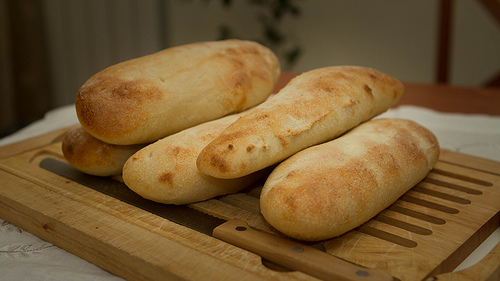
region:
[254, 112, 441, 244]
a loaf of bread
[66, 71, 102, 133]
a dark brown end of a bread loaf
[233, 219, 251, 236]
a bolt in the wood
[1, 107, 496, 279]
a brown wooden cutting board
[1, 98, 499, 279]
a white table cloth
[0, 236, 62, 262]
a pattern on the table cloth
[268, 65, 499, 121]
a brown wooden table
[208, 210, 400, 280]
a brown wooden handle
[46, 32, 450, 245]
a group of bread loaves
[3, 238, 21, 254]
a leaf pattern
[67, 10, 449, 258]
bread on a tray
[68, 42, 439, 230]
Fresh baked loaves of bread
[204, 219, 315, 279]
The handle of a knife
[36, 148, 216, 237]
The knife blade under the bread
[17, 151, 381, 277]
A knife in the bread tray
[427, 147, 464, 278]
Slits in the wooden trey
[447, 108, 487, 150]
A white table cloth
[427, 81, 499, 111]
The wooden dinner table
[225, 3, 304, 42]
Plant near the wall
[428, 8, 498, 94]
A chair at the table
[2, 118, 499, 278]
wood cutting board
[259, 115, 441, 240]
loaf of bread in pile of loaves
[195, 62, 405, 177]
loaf of bread in pile of loaves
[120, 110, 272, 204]
loaf of bread in pile of loaves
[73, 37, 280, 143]
loaf of bread in pile of loaves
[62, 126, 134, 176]
loaf of bread in pile of loaves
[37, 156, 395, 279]
sawtooth knife with wood handle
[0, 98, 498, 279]
white tablecloth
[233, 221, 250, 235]
top rivet of knife handle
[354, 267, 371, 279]
bottom rivet of knife handle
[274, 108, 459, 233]
light brown loaf of bread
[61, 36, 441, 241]
five small loaves of bread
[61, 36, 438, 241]
baked loaves of bread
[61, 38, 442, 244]
baked breads on a wooden board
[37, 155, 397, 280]
a cutting knife on a board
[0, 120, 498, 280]
a bread cooling and cutting board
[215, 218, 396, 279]
a brown wooden handle to a knife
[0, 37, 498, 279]
bread loaves on top of a cutting and cooling board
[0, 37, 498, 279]
a bread cutting board on top of a wooden table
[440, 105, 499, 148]
part of a white tablecloth on the table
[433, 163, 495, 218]
horizontal openings in the board for cooling breads